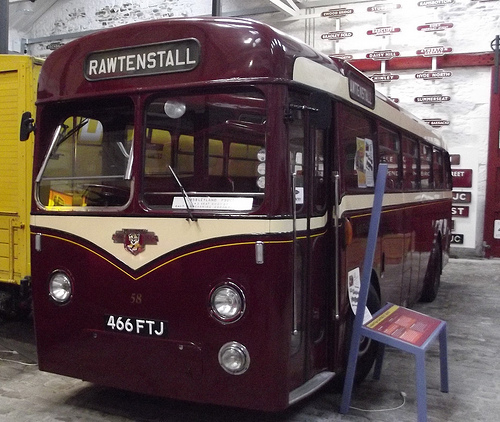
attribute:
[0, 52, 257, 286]
car —  train's,  yellow 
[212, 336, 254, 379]
headlights —  clear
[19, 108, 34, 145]
mirror — side-view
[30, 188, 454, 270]
stripe —  white,  design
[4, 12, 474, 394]
bus —  maroon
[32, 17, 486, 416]
bus —  maroon,  for city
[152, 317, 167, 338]
letter — J